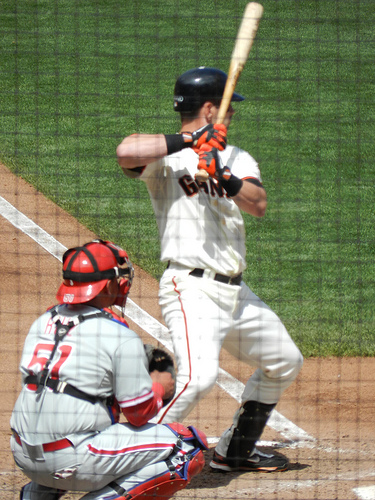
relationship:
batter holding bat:
[116, 70, 307, 477] [196, 1, 266, 186]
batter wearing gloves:
[116, 70, 307, 477] [189, 119, 229, 181]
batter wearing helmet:
[116, 70, 307, 477] [173, 66, 248, 114]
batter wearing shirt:
[116, 70, 307, 477] [142, 142, 268, 283]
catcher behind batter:
[9, 236, 214, 499] [116, 70, 307, 477]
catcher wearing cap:
[9, 236, 214, 499] [50, 238, 138, 308]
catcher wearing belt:
[9, 236, 214, 499] [5, 434, 76, 457]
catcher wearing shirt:
[9, 236, 214, 499] [5, 300, 156, 447]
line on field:
[0, 195, 318, 444] [0, 3, 373, 495]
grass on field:
[3, 1, 374, 367] [0, 3, 373, 495]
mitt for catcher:
[142, 342, 182, 410] [9, 236, 214, 499]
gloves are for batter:
[189, 119, 229, 181] [116, 70, 307, 477]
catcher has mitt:
[9, 236, 214, 499] [142, 342, 182, 410]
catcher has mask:
[9, 236, 214, 499] [117, 251, 136, 307]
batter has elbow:
[116, 70, 307, 477] [113, 140, 134, 163]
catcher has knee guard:
[9, 236, 214, 499] [177, 418, 213, 480]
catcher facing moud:
[9, 236, 214, 499] [188, 427, 374, 495]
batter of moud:
[116, 70, 307, 477] [188, 427, 374, 495]